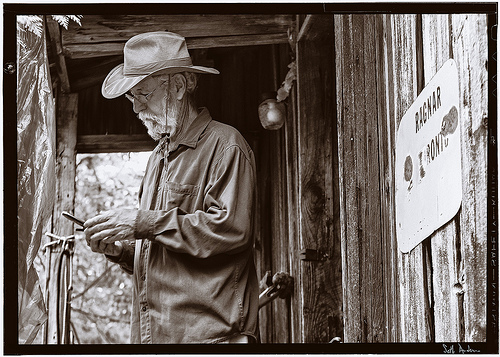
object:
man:
[84, 33, 262, 346]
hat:
[97, 29, 222, 102]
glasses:
[124, 87, 166, 100]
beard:
[139, 112, 178, 140]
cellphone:
[63, 212, 89, 223]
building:
[237, 16, 499, 315]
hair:
[177, 72, 199, 90]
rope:
[49, 238, 78, 347]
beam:
[50, 94, 74, 340]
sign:
[385, 62, 464, 254]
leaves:
[23, 26, 32, 39]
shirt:
[129, 112, 265, 339]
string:
[163, 78, 173, 152]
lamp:
[267, 99, 284, 122]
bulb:
[265, 102, 282, 125]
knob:
[160, 132, 168, 136]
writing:
[408, 106, 448, 119]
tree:
[80, 161, 127, 216]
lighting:
[256, 99, 286, 131]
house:
[222, 72, 477, 352]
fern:
[445, 270, 476, 297]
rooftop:
[45, 100, 278, 154]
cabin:
[245, 87, 475, 351]